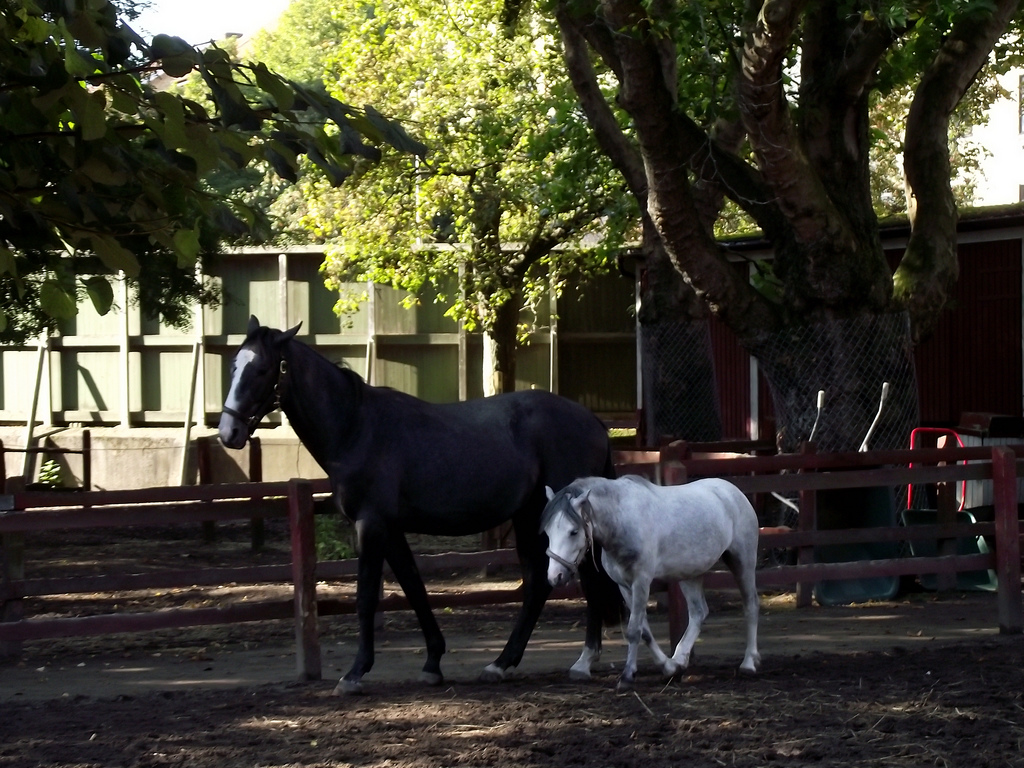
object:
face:
[218, 338, 281, 450]